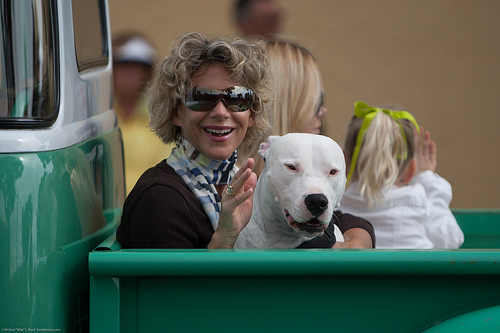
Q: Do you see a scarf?
A: Yes, there is a scarf.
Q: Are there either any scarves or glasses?
A: Yes, there is a scarf.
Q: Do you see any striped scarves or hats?
A: Yes, there is a striped scarf.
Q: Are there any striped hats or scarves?
A: Yes, there is a striped scarf.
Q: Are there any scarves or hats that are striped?
A: Yes, the scarf is striped.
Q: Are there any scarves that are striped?
A: Yes, there is a striped scarf.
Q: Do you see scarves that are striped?
A: Yes, there is a scarf that is striped.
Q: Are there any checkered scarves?
A: Yes, there is a checkered scarf.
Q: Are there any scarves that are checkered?
A: Yes, there is a scarf that is checkered.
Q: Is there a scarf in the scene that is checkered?
A: Yes, there is a scarf that is checkered.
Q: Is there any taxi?
A: Yes, there is a taxi.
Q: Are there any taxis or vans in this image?
A: Yes, there is a taxi.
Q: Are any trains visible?
A: No, there are no trains.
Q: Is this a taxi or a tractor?
A: This is a taxi.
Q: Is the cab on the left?
A: Yes, the cab is on the left of the image.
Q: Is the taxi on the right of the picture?
A: No, the taxi is on the left of the image.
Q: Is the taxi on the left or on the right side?
A: The taxi is on the left of the image.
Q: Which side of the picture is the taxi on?
A: The taxi is on the left of the image.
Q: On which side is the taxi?
A: The taxi is on the left of the image.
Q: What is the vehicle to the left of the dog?
A: The vehicle is a taxi.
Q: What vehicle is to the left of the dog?
A: The vehicle is a taxi.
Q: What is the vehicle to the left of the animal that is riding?
A: The vehicle is a taxi.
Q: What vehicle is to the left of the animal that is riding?
A: The vehicle is a taxi.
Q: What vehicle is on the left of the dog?
A: The vehicle is a taxi.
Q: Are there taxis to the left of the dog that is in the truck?
A: Yes, there is a taxi to the left of the dog.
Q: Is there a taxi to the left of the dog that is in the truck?
A: Yes, there is a taxi to the left of the dog.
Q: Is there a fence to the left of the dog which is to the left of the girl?
A: No, there is a taxi to the left of the dog.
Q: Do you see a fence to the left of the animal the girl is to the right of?
A: No, there is a taxi to the left of the dog.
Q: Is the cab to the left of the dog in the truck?
A: Yes, the cab is to the left of the dog.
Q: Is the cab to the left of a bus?
A: No, the cab is to the left of the dog.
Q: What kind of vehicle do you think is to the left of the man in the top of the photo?
A: The vehicle is a taxi.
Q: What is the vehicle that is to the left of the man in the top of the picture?
A: The vehicle is a taxi.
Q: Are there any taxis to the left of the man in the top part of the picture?
A: Yes, there is a taxi to the left of the man.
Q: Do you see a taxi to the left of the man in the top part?
A: Yes, there is a taxi to the left of the man.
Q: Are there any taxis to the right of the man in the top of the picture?
A: No, the taxi is to the left of the man.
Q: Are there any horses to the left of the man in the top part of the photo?
A: No, there is a taxi to the left of the man.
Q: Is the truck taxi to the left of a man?
A: Yes, the cab is to the left of a man.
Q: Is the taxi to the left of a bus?
A: No, the taxi is to the left of a man.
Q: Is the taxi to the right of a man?
A: No, the taxi is to the left of a man.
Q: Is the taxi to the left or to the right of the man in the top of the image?
A: The taxi is to the left of the man.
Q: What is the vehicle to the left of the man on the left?
A: The vehicle is a taxi.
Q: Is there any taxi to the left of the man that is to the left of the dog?
A: Yes, there is a taxi to the left of the man.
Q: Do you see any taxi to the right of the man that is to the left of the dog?
A: No, the taxi is to the left of the man.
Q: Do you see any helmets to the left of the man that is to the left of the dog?
A: No, there is a taxi to the left of the man.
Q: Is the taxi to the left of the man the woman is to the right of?
A: Yes, the taxi is to the left of the man.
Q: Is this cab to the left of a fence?
A: No, the cab is to the left of the man.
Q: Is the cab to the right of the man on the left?
A: No, the cab is to the left of the man.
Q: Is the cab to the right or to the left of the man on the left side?
A: The cab is to the left of the man.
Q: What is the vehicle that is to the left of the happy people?
A: The vehicle is a taxi.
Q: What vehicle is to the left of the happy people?
A: The vehicle is a taxi.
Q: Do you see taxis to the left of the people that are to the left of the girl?
A: Yes, there is a taxi to the left of the people.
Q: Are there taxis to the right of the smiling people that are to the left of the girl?
A: No, the taxi is to the left of the people.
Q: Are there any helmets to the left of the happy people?
A: No, there is a taxi to the left of the people.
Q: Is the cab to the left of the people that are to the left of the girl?
A: Yes, the cab is to the left of the people.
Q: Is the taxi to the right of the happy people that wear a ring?
A: No, the taxi is to the left of the people.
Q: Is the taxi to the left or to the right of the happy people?
A: The taxi is to the left of the people.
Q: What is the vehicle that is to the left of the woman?
A: The vehicle is a taxi.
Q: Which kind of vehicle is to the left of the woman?
A: The vehicle is a taxi.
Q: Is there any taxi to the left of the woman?
A: Yes, there is a taxi to the left of the woman.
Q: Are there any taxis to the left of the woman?
A: Yes, there is a taxi to the left of the woman.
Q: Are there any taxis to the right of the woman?
A: No, the taxi is to the left of the woman.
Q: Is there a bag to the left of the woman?
A: No, there is a taxi to the left of the woman.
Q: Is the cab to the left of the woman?
A: Yes, the cab is to the left of the woman.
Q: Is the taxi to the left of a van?
A: No, the taxi is to the left of the woman.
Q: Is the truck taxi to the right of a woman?
A: No, the taxi is to the left of a woman.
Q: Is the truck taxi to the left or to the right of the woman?
A: The taxi is to the left of the woman.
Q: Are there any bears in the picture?
A: No, there are no bears.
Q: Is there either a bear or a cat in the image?
A: No, there are no bears or cats.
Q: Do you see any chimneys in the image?
A: No, there are no chimneys.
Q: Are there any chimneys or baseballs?
A: No, there are no chimneys or baseballs.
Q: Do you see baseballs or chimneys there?
A: No, there are no chimneys or baseballs.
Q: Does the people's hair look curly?
A: Yes, the hair is curly.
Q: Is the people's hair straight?
A: No, the hair is curly.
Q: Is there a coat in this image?
A: Yes, there is a coat.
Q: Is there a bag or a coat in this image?
A: Yes, there is a coat.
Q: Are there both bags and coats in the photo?
A: No, there is a coat but no bags.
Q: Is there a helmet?
A: No, there are no helmets.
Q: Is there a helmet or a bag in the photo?
A: No, there are no helmets or bags.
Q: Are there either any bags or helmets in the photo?
A: No, there are no helmets or bags.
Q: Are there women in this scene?
A: Yes, there is a woman.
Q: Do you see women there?
A: Yes, there is a woman.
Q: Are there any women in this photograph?
A: Yes, there is a woman.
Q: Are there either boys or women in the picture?
A: Yes, there is a woman.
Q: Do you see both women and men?
A: Yes, there are both a woman and a man.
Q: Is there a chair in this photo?
A: No, there are no chairs.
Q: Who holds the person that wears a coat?
A: The woman holds the girl.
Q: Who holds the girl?
A: The woman holds the girl.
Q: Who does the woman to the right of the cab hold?
A: The woman holds the girl.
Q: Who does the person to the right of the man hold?
A: The woman holds the girl.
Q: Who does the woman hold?
A: The woman holds the girl.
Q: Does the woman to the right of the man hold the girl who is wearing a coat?
A: Yes, the woman holds the girl.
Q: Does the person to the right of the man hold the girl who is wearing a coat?
A: Yes, the woman holds the girl.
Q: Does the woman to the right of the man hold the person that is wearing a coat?
A: Yes, the woman holds the girl.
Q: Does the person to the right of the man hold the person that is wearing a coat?
A: Yes, the woman holds the girl.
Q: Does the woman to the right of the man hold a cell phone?
A: No, the woman holds the girl.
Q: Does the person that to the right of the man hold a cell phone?
A: No, the woman holds the girl.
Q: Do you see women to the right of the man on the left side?
A: Yes, there is a woman to the right of the man.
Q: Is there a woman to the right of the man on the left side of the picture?
A: Yes, there is a woman to the right of the man.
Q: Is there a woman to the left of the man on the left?
A: No, the woman is to the right of the man.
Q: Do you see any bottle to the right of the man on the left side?
A: No, there is a woman to the right of the man.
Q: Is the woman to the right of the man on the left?
A: Yes, the woman is to the right of the man.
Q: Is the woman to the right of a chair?
A: No, the woman is to the right of the man.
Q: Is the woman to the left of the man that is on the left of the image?
A: No, the woman is to the right of the man.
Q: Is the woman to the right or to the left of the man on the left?
A: The woman is to the right of the man.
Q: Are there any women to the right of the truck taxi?
A: Yes, there is a woman to the right of the taxi cab.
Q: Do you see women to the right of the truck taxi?
A: Yes, there is a woman to the right of the taxi cab.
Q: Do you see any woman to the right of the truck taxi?
A: Yes, there is a woman to the right of the taxi cab.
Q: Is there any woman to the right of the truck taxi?
A: Yes, there is a woman to the right of the taxi cab.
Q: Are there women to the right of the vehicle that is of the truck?
A: Yes, there is a woman to the right of the taxi cab.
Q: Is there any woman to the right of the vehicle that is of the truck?
A: Yes, there is a woman to the right of the taxi cab.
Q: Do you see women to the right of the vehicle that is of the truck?
A: Yes, there is a woman to the right of the taxi cab.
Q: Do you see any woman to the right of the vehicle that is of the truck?
A: Yes, there is a woman to the right of the taxi cab.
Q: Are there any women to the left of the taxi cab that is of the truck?
A: No, the woman is to the right of the taxi.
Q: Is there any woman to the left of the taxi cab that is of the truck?
A: No, the woman is to the right of the taxi.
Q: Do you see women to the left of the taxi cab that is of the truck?
A: No, the woman is to the right of the taxi.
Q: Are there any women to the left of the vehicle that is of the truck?
A: No, the woman is to the right of the taxi.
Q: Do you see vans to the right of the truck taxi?
A: No, there is a woman to the right of the taxi.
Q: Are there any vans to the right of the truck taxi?
A: No, there is a woman to the right of the taxi.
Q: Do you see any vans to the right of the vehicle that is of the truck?
A: No, there is a woman to the right of the taxi.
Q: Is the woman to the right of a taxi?
A: Yes, the woman is to the right of a taxi.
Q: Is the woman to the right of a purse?
A: No, the woman is to the right of a taxi.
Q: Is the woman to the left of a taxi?
A: No, the woman is to the right of a taxi.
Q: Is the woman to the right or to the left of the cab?
A: The woman is to the right of the cab.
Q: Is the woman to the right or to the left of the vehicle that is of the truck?
A: The woman is to the right of the cab.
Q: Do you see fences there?
A: No, there are no fences.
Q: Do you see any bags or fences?
A: No, there are no fences or bags.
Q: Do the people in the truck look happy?
A: Yes, the people are happy.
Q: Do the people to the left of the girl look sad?
A: No, the people are happy.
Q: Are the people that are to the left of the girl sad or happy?
A: The people are happy.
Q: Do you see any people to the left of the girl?
A: Yes, there are people to the left of the girl.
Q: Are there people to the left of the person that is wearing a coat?
A: Yes, there are people to the left of the girl.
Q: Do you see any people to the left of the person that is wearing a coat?
A: Yes, there are people to the left of the girl.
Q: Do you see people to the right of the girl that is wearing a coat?
A: No, the people are to the left of the girl.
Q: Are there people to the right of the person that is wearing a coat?
A: No, the people are to the left of the girl.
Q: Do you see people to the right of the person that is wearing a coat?
A: No, the people are to the left of the girl.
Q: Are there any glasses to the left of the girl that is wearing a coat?
A: No, there are people to the left of the girl.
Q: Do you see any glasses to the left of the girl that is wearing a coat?
A: No, there are people to the left of the girl.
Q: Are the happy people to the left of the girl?
A: Yes, the people are to the left of the girl.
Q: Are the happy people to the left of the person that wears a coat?
A: Yes, the people are to the left of the girl.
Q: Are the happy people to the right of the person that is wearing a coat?
A: No, the people are to the left of the girl.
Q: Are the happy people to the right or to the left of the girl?
A: The people are to the left of the girl.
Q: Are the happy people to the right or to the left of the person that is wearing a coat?
A: The people are to the left of the girl.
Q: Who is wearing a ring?
A: The people are wearing a ring.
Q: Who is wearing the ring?
A: The people are wearing a ring.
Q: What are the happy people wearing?
A: The people are wearing a ring.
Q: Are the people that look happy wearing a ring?
A: Yes, the people are wearing a ring.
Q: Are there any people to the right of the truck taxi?
A: Yes, there are people to the right of the taxi cab.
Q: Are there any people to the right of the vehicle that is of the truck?
A: Yes, there are people to the right of the taxi cab.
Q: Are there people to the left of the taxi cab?
A: No, the people are to the right of the taxi cab.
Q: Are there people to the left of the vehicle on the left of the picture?
A: No, the people are to the right of the taxi cab.